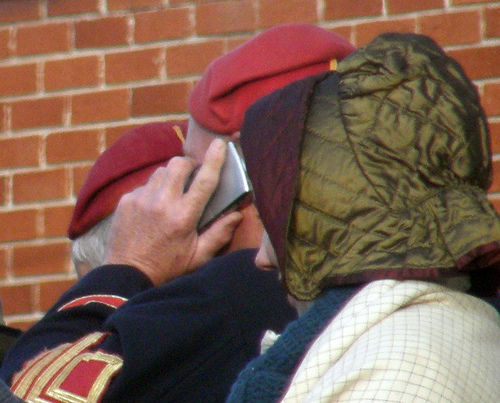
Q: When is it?
A: Day time.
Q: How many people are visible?
A: Three.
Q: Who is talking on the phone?
A: A man.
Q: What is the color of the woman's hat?
A: Green.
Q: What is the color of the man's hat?
A: Red.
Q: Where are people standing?
A: Near a brick wall.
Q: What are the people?
A: Adults.